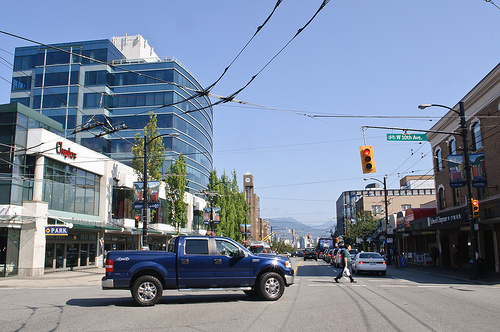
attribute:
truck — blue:
[100, 234, 298, 310]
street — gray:
[164, 249, 455, 331]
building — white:
[0, 113, 108, 281]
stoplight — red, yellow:
[362, 144, 376, 173]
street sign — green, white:
[389, 132, 429, 143]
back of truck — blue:
[112, 253, 176, 283]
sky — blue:
[28, 3, 498, 136]